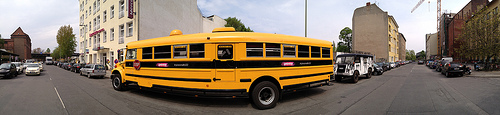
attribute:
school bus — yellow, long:
[133, 33, 342, 98]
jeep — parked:
[331, 53, 381, 83]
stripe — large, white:
[55, 75, 74, 111]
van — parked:
[73, 60, 106, 75]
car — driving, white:
[22, 64, 41, 77]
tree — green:
[222, 0, 248, 30]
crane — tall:
[411, 0, 448, 30]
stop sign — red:
[127, 58, 142, 69]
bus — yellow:
[265, 17, 350, 89]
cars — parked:
[1, 55, 100, 79]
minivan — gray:
[72, 60, 91, 82]